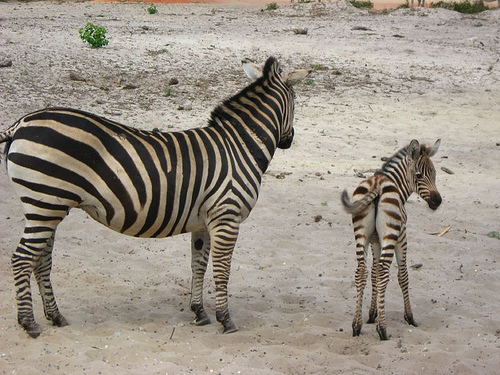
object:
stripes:
[28, 112, 250, 237]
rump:
[7, 109, 71, 196]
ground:
[0, 0, 500, 375]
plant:
[78, 21, 108, 47]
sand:
[26, 24, 225, 99]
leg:
[394, 248, 411, 314]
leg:
[207, 229, 239, 308]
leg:
[32, 233, 59, 316]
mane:
[207, 55, 280, 128]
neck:
[218, 79, 283, 164]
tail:
[0, 128, 12, 144]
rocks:
[69, 68, 191, 110]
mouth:
[427, 201, 439, 210]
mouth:
[278, 139, 292, 149]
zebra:
[0, 58, 294, 339]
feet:
[191, 312, 237, 334]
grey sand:
[0, 0, 500, 375]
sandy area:
[0, 0, 500, 375]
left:
[2, 0, 180, 375]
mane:
[382, 146, 408, 172]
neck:
[390, 147, 411, 197]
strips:
[104, 145, 174, 208]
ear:
[426, 138, 442, 157]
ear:
[409, 139, 420, 158]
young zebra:
[340, 139, 442, 341]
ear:
[243, 64, 260, 81]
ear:
[284, 70, 312, 85]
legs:
[9, 213, 66, 323]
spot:
[194, 238, 204, 251]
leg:
[190, 228, 210, 308]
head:
[265, 60, 295, 149]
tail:
[341, 190, 377, 213]